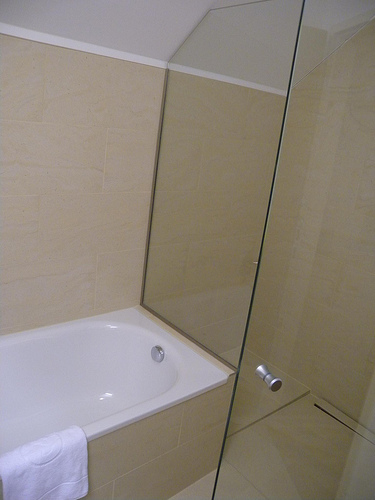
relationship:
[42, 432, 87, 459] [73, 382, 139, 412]
towel on tub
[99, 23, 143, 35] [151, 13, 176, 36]
part of ceiling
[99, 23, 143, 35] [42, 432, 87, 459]
part of towel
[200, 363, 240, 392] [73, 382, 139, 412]
edge of tub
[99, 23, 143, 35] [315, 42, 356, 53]
part of glass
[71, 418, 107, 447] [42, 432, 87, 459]
edge of towel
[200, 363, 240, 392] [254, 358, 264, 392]
edge of handle